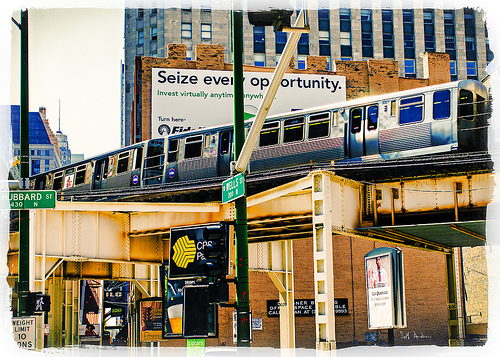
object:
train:
[20, 80, 499, 194]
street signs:
[8, 191, 55, 210]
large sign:
[151, 70, 347, 142]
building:
[134, 42, 450, 139]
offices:
[124, 1, 231, 56]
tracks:
[129, 148, 490, 192]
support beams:
[308, 171, 342, 352]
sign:
[167, 226, 227, 278]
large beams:
[364, 180, 403, 223]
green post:
[237, 201, 250, 344]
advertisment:
[364, 251, 400, 327]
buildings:
[4, 105, 60, 176]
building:
[50, 98, 72, 165]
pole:
[57, 99, 63, 131]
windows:
[362, 47, 374, 57]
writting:
[399, 329, 433, 339]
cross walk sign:
[29, 291, 51, 311]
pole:
[17, 210, 31, 315]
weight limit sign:
[12, 317, 37, 347]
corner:
[8, 304, 87, 352]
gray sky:
[0, 0, 126, 155]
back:
[0, 0, 500, 157]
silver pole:
[230, 7, 317, 173]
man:
[35, 297, 44, 311]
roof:
[10, 105, 50, 147]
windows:
[185, 134, 203, 159]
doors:
[362, 103, 379, 154]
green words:
[157, 89, 178, 96]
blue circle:
[168, 168, 176, 179]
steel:
[361, 161, 428, 170]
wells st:
[226, 179, 239, 192]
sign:
[220, 172, 246, 204]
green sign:
[187, 339, 206, 347]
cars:
[166, 81, 486, 182]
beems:
[405, 179, 437, 212]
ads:
[104, 283, 131, 303]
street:
[0, 329, 500, 357]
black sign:
[267, 298, 350, 317]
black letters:
[157, 69, 199, 86]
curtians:
[341, 39, 351, 46]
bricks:
[384, 84, 394, 91]